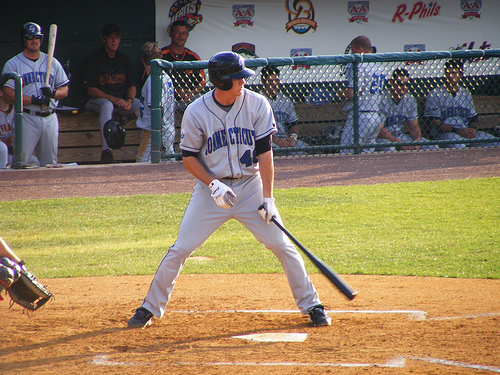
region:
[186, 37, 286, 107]
the head of a man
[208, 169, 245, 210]
the hand of a man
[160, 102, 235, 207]
the arm of a man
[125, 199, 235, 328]
the leg of a man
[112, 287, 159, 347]
the foot of a man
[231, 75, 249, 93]
the nose of a man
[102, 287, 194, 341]
a man wearing shoes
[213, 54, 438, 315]
a man holding a bat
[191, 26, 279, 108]
a man wearing a hat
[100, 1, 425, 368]
a man playing baseball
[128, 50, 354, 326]
Batter standing near home plate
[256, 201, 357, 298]
Black bat in batters left hand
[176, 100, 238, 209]
Batters right arm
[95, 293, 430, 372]
Chalk box drawn around home plate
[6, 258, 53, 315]
Catchers glove in lower left of photo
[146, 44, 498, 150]
Green chain link fence at edge of field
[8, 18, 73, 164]
Man standing in background holding bat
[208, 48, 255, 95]
Helmet on head of man at bat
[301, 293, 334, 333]
left foot of man at bat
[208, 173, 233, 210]
right hand of man at bat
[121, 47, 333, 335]
batter standing with wide legs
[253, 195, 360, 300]
black bat in left hand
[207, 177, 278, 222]
white gloves on batter's hands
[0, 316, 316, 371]
shadow of batter's legs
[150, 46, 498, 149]
chain-link fence behind field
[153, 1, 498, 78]
product logos on white board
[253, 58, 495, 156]
players sitting behind fence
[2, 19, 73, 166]
player holding white baseball bat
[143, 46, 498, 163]
greenish railing surrounds fence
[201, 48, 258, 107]
batter looking over left shoulder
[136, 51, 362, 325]
baseball player with his bat ready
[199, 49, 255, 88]
hard black baseball helmet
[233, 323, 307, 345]
white marker for home base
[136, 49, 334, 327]
baseball player in a white uniform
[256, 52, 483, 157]
players sitting on the bench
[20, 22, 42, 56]
baseball player wearing sunglasses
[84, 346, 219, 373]
lines painted on the ground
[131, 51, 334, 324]
baseball player with his legs spread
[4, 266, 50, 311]
mitt of the catcher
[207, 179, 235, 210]
bright white glove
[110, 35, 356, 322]
man wearing a helmet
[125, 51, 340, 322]
man wearing white shirt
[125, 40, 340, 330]
man wearing white pants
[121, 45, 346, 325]
man holding a bat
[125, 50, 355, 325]
man wearing black shoes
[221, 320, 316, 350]
plate on a field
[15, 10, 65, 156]
man wearing a helmet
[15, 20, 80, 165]
man holding a bat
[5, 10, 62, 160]
man wearing white shirt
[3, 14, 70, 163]
man wearing white pants